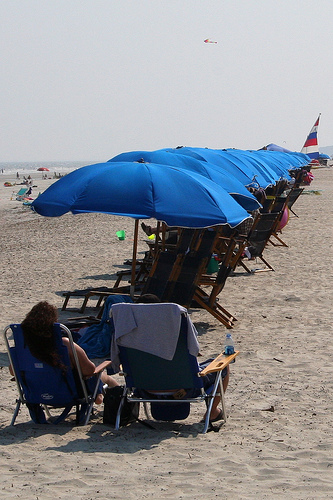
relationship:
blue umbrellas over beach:
[30, 159, 252, 232] [285, 319, 331, 382]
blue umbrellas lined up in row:
[30, 159, 252, 232] [26, 142, 312, 305]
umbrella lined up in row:
[219, 148, 277, 187] [26, 142, 312, 305]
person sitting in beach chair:
[18, 299, 122, 404] [3, 322, 113, 428]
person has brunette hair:
[18, 299, 122, 404] [21, 300, 71, 374]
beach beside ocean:
[0, 161, 331, 498] [0, 159, 107, 170]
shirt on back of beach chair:
[107, 303, 202, 376] [110, 303, 239, 438]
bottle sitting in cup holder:
[224, 334, 235, 363] [220, 351, 236, 357]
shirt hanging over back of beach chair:
[107, 303, 202, 376] [110, 302, 240, 434]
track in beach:
[42, 478, 90, 490] [0, 161, 331, 498]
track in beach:
[163, 468, 202, 480] [0, 161, 331, 498]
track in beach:
[250, 468, 288, 476] [0, 161, 331, 498]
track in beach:
[254, 438, 298, 453] [0, 161, 331, 498]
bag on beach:
[102, 384, 141, 428] [0, 161, 331, 498]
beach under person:
[0, 161, 331, 498] [18, 299, 122, 404]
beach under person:
[0, 161, 331, 498] [132, 293, 230, 425]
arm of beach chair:
[200, 349, 239, 378] [110, 302, 240, 434]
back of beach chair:
[110, 300, 206, 403] [110, 302, 240, 434]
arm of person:
[60, 336, 96, 375] [18, 299, 122, 404]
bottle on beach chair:
[224, 334, 237, 366] [110, 302, 240, 434]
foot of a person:
[140, 221, 152, 237] [142, 222, 179, 237]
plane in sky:
[205, 35, 220, 48] [24, 32, 320, 119]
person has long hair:
[18, 299, 122, 404] [25, 302, 55, 358]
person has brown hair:
[18, 299, 122, 404] [22, 299, 69, 366]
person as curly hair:
[18, 299, 122, 404] [28, 303, 56, 359]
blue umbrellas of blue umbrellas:
[30, 159, 252, 232] [35, 159, 248, 232]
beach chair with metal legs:
[110, 302, 240, 434] [201, 372, 228, 429]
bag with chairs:
[102, 384, 140, 426] [108, 299, 235, 433]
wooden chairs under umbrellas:
[133, 246, 217, 314] [30, 154, 246, 293]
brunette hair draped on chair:
[24, 309, 54, 356] [1, 316, 99, 423]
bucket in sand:
[116, 230, 126, 241] [286, 328, 313, 344]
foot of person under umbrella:
[140, 221, 152, 237] [30, 162, 261, 278]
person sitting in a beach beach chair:
[18, 299, 122, 404] [3, 322, 113, 427]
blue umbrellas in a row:
[35, 159, 248, 232] [32, 141, 317, 235]